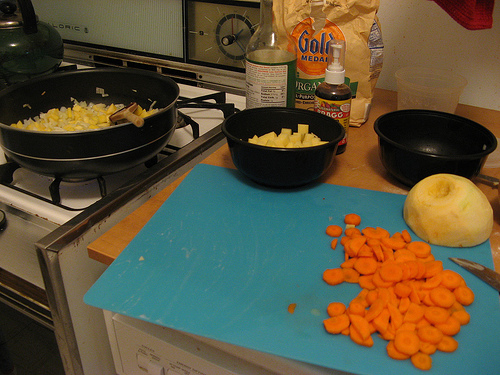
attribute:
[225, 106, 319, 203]
bowl — present, here, black, cereal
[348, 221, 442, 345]
food — piled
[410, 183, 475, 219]
potato — half, large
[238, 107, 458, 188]
bowls — black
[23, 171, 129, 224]
stove — back, old, gas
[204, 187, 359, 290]
mat — blue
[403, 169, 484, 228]
parsnip — cubed, half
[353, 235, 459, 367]
carrots — sliced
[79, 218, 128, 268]
corner — upper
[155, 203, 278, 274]
pad — thin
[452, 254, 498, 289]
knife — medium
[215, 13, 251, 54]
dial — timer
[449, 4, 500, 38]
towel — red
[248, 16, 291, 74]
container — clear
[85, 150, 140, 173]
pan — black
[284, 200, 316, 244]
board — blue, chopping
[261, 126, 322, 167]
potatoes — diced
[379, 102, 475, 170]
bowl — empty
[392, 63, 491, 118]
bowl — plastic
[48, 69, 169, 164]
pots — cooking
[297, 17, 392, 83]
packet — flour